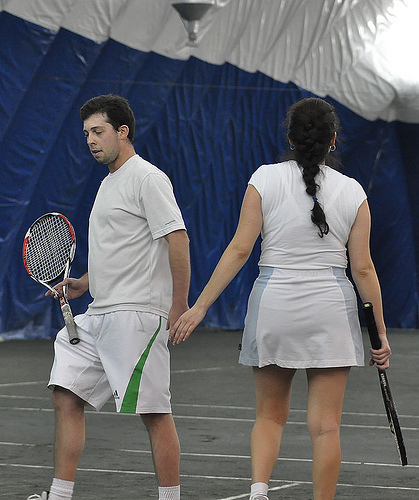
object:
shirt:
[83, 153, 188, 316]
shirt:
[247, 158, 367, 271]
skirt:
[236, 263, 365, 372]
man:
[25, 94, 192, 500]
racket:
[20, 210, 80, 345]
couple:
[23, 92, 388, 500]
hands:
[168, 302, 205, 344]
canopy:
[0, 0, 418, 342]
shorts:
[45, 308, 174, 414]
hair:
[286, 97, 343, 239]